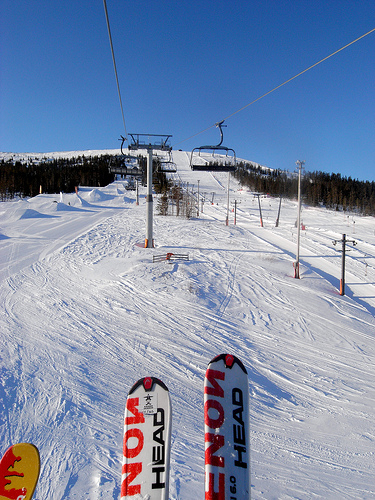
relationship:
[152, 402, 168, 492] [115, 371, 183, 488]
edge of ski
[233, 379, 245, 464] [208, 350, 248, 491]
edge of ski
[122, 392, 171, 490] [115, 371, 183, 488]
writing on ski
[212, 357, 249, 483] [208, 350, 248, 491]
writing on ski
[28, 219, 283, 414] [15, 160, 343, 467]
tracks crisscrossing a slope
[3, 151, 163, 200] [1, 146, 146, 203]
stand of trees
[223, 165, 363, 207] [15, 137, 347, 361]
trees growing along a slope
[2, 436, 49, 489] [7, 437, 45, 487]
edge of ski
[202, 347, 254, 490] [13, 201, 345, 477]
board on top of snow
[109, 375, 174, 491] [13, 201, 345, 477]
ski on the snow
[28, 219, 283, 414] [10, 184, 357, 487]
tracks left in snow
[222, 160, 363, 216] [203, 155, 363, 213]
forest of trees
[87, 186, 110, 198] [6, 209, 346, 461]
hill made out of snow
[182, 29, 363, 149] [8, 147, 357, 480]
wire above a ski slope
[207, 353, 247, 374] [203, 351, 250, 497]
tip on ski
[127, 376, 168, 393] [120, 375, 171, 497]
tip on ski